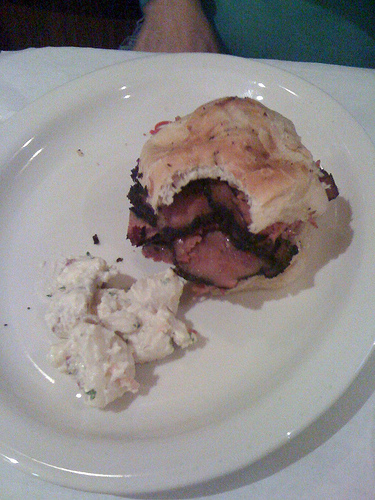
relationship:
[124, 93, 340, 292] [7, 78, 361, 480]
sandwich on plate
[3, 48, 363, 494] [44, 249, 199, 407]
plate with food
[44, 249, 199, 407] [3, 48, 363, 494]
food on plate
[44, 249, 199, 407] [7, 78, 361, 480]
food on plate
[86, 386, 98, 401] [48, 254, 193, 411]
part of food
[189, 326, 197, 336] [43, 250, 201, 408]
part of food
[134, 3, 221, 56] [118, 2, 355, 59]
hand of a person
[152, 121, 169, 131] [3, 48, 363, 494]
thing on plate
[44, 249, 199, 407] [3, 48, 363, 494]
food on a plate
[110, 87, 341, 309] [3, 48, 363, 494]
food on a plate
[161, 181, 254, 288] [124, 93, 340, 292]
meat on a sandwich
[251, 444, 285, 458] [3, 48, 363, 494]
edge of a plate